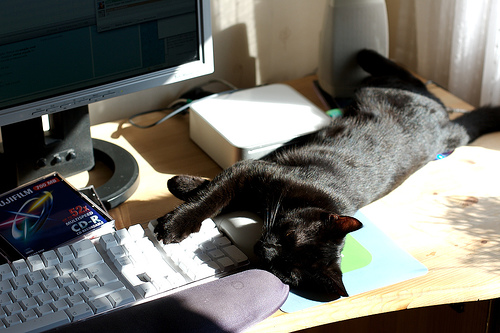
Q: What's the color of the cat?
A: Black.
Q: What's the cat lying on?
A: Table.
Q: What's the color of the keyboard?
A: White.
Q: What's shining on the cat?
A: Sun.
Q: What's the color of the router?
A: White.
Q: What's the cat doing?
A: Lying down.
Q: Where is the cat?
A: Laying on a desk.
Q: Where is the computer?
A: On the desk.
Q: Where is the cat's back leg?
A: Touching the speaker.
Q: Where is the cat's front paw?
A: On the computer keyboard.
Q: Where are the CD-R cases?
A: Near the computer monitor.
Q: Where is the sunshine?
A: Coming in the window.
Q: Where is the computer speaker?
A: On the corner of the desk.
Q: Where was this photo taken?
A: In a home office.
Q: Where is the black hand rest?
A: By the computer keyboard.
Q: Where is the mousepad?
A: Under cat.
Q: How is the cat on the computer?
A: Sleeping.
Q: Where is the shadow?
A: To the far right.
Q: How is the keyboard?
A: White.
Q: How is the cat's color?
A: Black.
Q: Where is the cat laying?
A: In sun.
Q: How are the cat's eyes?
A: Closed.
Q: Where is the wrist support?
A: On desk.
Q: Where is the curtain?
A: Behind the cat.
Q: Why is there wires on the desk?
A: For computer.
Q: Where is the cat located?
A: Laying on the desk.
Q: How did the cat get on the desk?
A: By jumping.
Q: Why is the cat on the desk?
A: Sleeping.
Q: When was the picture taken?
A: Daytime.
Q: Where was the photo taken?
A: In a room.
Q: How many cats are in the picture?
A: One.